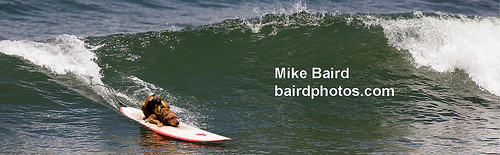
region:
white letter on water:
[274, 63, 284, 79]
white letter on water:
[286, 64, 291, 81]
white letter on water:
[290, 65, 300, 79]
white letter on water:
[299, 67, 306, 79]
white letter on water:
[312, 66, 320, 78]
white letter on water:
[323, 68, 331, 79]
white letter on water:
[330, 65, 332, 80]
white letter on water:
[334, 69, 339, 79]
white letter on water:
[339, 66, 349, 78]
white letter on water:
[380, 86, 393, 96]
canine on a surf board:
[83, 74, 240, 151]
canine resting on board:
[136, 95, 183, 129]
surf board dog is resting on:
[110, 103, 236, 145]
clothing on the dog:
[141, 95, 166, 110]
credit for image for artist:
[274, 56, 401, 103]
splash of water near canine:
[13, 42, 89, 82]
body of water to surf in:
[8, 6, 491, 150]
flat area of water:
[9, 6, 98, 25]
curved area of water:
[214, 11, 443, 78]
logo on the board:
[192, 128, 220, 140]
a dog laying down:
[142, 90, 180, 125]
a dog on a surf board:
[119, 97, 232, 142]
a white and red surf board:
[119, 106, 231, 142]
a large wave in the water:
[204, 15, 496, 91]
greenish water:
[281, 98, 438, 148]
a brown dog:
[138, 93, 178, 126]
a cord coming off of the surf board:
[83, 68, 127, 107]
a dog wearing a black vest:
[140, 93, 178, 125]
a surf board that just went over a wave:
[8, 33, 229, 153]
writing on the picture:
[272, 65, 394, 97]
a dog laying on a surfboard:
[115, 90, 235, 154]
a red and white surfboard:
[107, 99, 229, 148]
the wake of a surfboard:
[58, 48, 127, 113]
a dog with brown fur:
[142, 92, 181, 131]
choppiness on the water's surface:
[408, 88, 448, 127]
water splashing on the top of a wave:
[237, 5, 323, 35]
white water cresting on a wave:
[403, 14, 480, 72]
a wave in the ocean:
[24, 20, 442, 107]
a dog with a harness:
[141, 95, 166, 116]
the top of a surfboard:
[176, 123, 221, 140]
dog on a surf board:
[108, 90, 245, 147]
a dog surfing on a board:
[91, 81, 240, 152]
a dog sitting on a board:
[130, 98, 185, 128]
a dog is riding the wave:
[14, 34, 253, 152]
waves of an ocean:
[16, 8, 482, 81]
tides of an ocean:
[9, 11, 407, 59]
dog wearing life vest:
[131, 93, 184, 133]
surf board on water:
[98, 85, 241, 153]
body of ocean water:
[93, 8, 129, 33]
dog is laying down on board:
[114, 88, 246, 154]